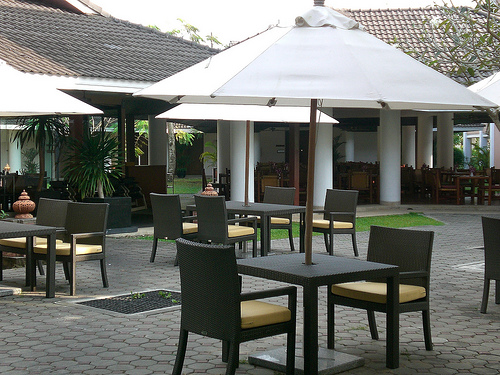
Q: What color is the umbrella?
A: White.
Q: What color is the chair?
A: Black.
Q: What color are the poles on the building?
A: White.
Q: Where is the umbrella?
A: Above the table.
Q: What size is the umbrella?
A: Large.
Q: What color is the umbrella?
A: White.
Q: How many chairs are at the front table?
A: Two.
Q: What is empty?
A: The chairs.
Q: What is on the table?
A: The table is empty.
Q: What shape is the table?
A: Square.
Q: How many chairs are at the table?
A: Two.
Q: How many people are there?
A: None.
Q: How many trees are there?
A: Two.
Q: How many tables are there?
A: Three.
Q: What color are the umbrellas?
A: White.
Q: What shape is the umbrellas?
A: Round.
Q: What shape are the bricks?
A: Round.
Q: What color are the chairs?
A: Black.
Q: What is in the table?
A: An umbrella pole.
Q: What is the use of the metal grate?
A: Water drainage.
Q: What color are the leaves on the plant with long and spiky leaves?
A: Green.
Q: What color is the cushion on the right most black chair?
A: Yellow.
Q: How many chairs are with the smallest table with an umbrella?
A: Two.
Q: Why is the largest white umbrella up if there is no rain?
A: To provide shade.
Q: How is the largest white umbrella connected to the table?
A: Pole.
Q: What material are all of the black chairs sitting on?
A: Brick.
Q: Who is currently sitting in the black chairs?
A: No one.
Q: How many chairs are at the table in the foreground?
A: Two.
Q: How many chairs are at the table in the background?
A: Four.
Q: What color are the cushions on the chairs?
A: Yellow.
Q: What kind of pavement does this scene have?
A: Stone.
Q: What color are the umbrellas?
A: White.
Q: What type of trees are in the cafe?
A: Palm trees.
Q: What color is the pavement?
A: Grey.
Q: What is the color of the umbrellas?
A: White.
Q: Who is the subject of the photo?
A: The patio.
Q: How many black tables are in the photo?
A: 3.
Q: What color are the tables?
A: Black.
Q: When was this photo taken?
A: During the day.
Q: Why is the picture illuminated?
A: Because it is daytime.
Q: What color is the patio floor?
A: Gray.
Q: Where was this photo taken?
A: Outside dining room patio.